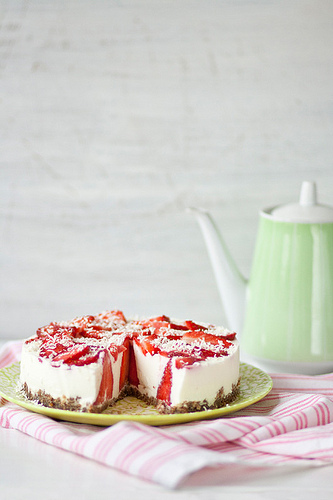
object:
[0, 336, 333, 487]
napkin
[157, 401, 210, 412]
crust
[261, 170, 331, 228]
lid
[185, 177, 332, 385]
jug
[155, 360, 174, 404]
strawberry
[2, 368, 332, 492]
napkin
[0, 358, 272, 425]
plate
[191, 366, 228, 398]
surface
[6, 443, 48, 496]
table top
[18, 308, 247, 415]
pie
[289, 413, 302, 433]
stripes